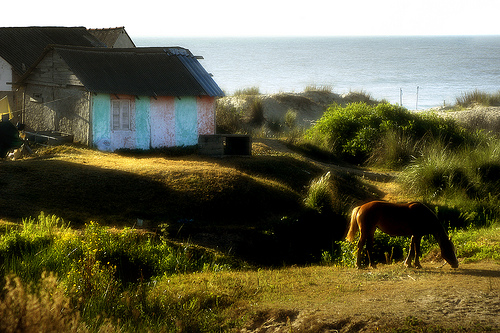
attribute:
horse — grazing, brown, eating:
[346, 195, 461, 272]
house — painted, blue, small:
[5, 24, 223, 154]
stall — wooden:
[194, 132, 254, 164]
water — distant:
[128, 34, 499, 109]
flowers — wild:
[57, 216, 131, 317]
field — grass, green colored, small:
[5, 87, 500, 331]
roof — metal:
[24, 42, 231, 101]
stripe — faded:
[145, 95, 179, 144]